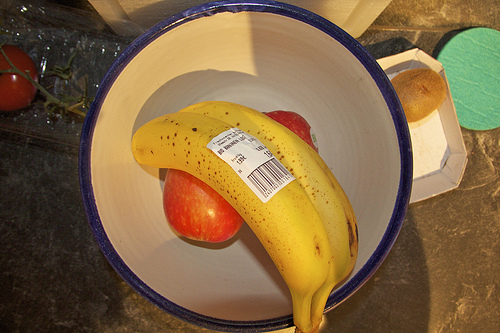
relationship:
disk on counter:
[435, 25, 499, 132] [2, 2, 498, 329]